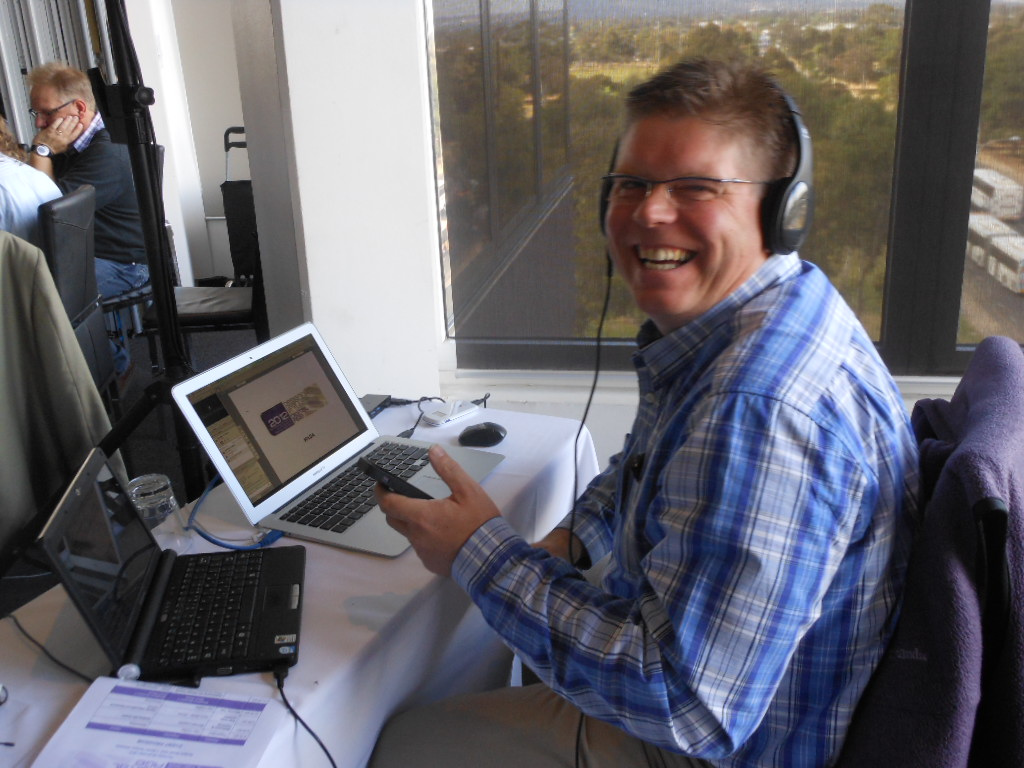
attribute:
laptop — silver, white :
[168, 319, 503, 559]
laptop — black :
[32, 448, 305, 682]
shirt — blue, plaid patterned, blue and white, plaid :
[448, 261, 915, 763]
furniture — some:
[74, 303, 1016, 764]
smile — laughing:
[627, 234, 703, 267]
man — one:
[614, 61, 848, 520]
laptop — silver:
[186, 303, 498, 554]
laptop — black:
[52, 448, 336, 688]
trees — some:
[502, 13, 922, 314]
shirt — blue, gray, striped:
[543, 297, 904, 749]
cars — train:
[968, 167, 1021, 347]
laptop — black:
[30, 437, 309, 671]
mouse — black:
[454, 419, 502, 452]